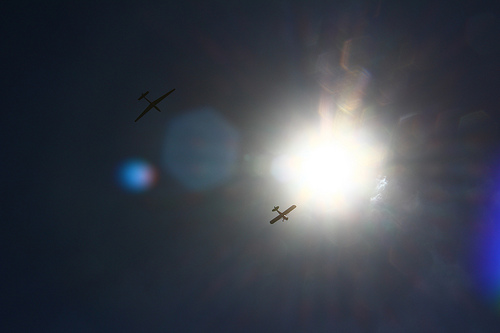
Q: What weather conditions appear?
A: It is clear.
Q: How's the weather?
A: It is clear.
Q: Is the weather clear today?
A: Yes, it is clear.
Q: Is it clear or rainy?
A: It is clear.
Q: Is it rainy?
A: No, it is clear.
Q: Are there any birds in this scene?
A: No, there are no birds.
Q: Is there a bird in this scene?
A: No, there are no birds.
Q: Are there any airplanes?
A: Yes, there is an airplane.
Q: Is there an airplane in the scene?
A: Yes, there is an airplane.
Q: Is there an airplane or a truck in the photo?
A: Yes, there is an airplane.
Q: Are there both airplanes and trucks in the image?
A: No, there is an airplane but no trucks.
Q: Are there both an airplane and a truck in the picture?
A: No, there is an airplane but no trucks.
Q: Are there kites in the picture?
A: No, there are no kites.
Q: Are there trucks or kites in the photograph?
A: No, there are no kites or trucks.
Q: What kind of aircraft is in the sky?
A: The aircraft is an airplane.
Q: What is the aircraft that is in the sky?
A: The aircraft is an airplane.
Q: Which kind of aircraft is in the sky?
A: The aircraft is an airplane.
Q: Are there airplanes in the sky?
A: Yes, there is an airplane in the sky.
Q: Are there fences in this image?
A: No, there are no fences.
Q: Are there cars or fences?
A: No, there are no fences or cars.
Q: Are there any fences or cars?
A: No, there are no fences or cars.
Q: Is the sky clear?
A: Yes, the sky is clear.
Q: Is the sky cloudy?
A: No, the sky is clear.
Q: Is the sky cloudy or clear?
A: The sky is clear.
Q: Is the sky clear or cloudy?
A: The sky is clear.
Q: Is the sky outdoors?
A: Yes, the sky is outdoors.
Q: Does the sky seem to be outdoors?
A: Yes, the sky is outdoors.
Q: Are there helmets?
A: No, there are no helmets.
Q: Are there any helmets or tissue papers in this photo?
A: No, there are no helmets or tissue papers.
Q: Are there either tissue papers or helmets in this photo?
A: No, there are no helmets or tissue papers.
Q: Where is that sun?
A: The sun is in the sky.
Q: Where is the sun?
A: The sun is in the sky.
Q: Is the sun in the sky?
A: Yes, the sun is in the sky.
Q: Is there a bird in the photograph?
A: No, there are no birds.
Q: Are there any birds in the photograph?
A: No, there are no birds.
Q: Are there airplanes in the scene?
A: Yes, there is an airplane.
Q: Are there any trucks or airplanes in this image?
A: Yes, there is an airplane.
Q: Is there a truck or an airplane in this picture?
A: Yes, there is an airplane.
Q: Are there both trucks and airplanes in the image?
A: No, there is an airplane but no trucks.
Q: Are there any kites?
A: No, there are no kites.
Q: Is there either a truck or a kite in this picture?
A: No, there are no kites or trucks.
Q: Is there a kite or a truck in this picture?
A: No, there are no kites or trucks.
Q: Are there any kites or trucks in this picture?
A: No, there are no kites or trucks.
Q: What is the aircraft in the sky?
A: The aircraft is an airplane.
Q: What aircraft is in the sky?
A: The aircraft is an airplane.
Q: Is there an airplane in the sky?
A: Yes, there is an airplane in the sky.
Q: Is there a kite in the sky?
A: No, there is an airplane in the sky.